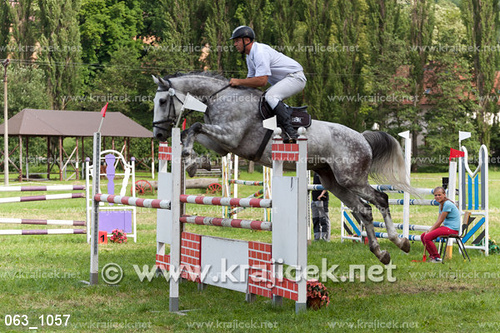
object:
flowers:
[307, 279, 330, 311]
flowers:
[110, 228, 128, 243]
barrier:
[89, 125, 312, 313]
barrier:
[372, 120, 492, 259]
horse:
[150, 69, 425, 264]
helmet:
[230, 25, 256, 54]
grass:
[0, 162, 500, 333]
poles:
[270, 126, 309, 312]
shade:
[0, 107, 161, 138]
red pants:
[421, 226, 460, 259]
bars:
[93, 193, 170, 208]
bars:
[180, 194, 271, 232]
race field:
[1, 73, 500, 333]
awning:
[0, 107, 154, 181]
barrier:
[0, 131, 104, 284]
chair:
[439, 211, 476, 264]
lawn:
[0, 171, 500, 333]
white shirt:
[246, 42, 303, 84]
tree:
[0, 0, 500, 173]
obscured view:
[0, 1, 497, 176]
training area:
[1, 80, 500, 333]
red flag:
[92, 100, 110, 171]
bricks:
[154, 231, 298, 302]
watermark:
[101, 258, 398, 284]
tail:
[361, 129, 423, 204]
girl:
[420, 186, 462, 264]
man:
[227, 25, 307, 145]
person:
[310, 167, 331, 242]